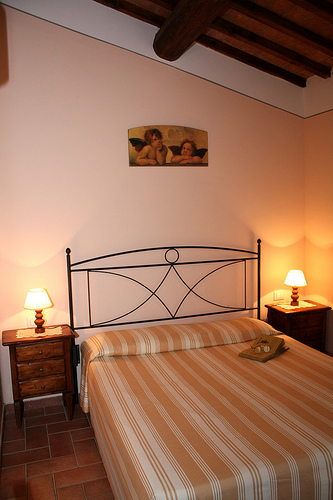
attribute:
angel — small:
[168, 139, 207, 164]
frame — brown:
[34, 311, 44, 333]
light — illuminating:
[283, 265, 304, 308]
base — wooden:
[30, 309, 48, 333]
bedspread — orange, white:
[79, 315, 332, 499]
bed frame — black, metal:
[52, 233, 280, 412]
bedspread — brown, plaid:
[67, 338, 332, 472]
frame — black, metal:
[59, 233, 265, 346]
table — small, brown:
[267, 294, 331, 353]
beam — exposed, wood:
[145, 5, 218, 62]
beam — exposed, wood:
[142, 5, 311, 81]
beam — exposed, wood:
[225, 10, 324, 65]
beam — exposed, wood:
[264, 5, 324, 42]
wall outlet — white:
[271, 285, 287, 304]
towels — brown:
[236, 330, 289, 364]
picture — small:
[126, 123, 207, 168]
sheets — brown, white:
[23, 288, 331, 499]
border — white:
[12, 1, 332, 116]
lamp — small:
[283, 264, 305, 306]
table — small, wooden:
[264, 296, 331, 356]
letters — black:
[258, 337, 270, 342]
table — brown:
[3, 325, 80, 426]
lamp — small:
[24, 284, 54, 333]